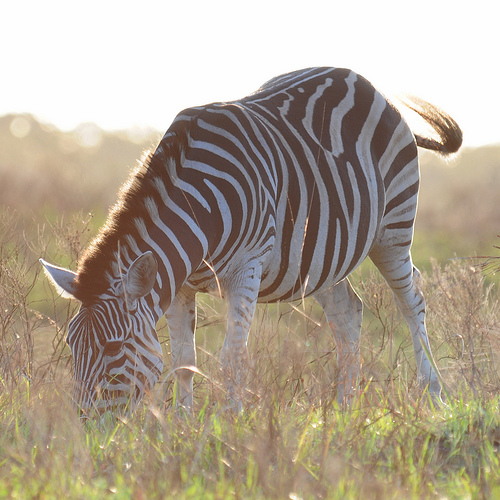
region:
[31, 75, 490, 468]
Zebra standing in the forest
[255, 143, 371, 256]
Black and white color stripes of the zebra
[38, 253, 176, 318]
Large upright ears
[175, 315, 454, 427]
Legs of the zebra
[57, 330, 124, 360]
Eyes of the zebra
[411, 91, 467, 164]
Tail of the zebra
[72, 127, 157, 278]
Black and white color mane of the zebra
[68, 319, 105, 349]
Forehead of the zebra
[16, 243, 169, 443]
Head of the zebra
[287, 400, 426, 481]
Green and brown color grass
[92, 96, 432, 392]
black and white zebra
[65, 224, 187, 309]
zebra has white ears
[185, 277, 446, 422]
zebra has white legs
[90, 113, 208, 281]
black and white mane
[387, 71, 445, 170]
zebra has black tail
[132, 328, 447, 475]
green and brown grass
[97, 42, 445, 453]
zebra is eating grass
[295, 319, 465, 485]
grass is long and wavy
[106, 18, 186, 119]
grey and bright sky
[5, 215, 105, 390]
long stems on weeds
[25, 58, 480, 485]
the zebra is in a field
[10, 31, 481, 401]
a zebra is in the grass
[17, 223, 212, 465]
the mouth of the zebra is covered by grass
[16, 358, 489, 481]
the grass is green and brown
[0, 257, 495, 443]
some of the grass is yellow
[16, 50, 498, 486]
this is a grazing zebra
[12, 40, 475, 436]
the zebra is grazing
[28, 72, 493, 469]
this is a black and white zebra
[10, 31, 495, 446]
the zebra has stripes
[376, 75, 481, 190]
this is the zebra's tail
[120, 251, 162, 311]
ear of a striped zebra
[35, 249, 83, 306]
ear of a striped zebra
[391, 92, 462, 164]
black tail of a striped zebra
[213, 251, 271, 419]
leg of a striped zebra eating grass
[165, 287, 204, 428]
leg of a striped zebra eating grass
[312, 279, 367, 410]
leg of a striped zebra eating grass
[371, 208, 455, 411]
leg of a striped zebra eating grass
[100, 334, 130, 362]
eye of a striped zebra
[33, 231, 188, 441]
head of a striped zebra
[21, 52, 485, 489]
striped zebra cropping grass